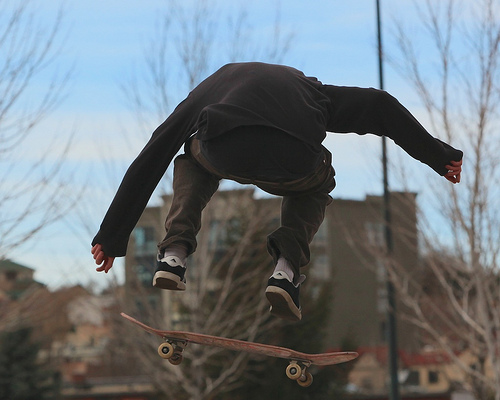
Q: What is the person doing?
A: Skateboarding.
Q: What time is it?
A: Afternoon.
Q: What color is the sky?
A: Blue.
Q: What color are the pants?
A: Brown.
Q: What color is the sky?
A: Blue.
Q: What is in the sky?
A: Clouds.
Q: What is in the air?
A: Skateboard.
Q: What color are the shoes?
A: Black and white.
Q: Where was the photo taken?
A: Outdoors somewhere.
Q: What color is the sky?
A: Blue.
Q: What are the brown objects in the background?
A: Buildings.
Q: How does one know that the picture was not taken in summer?
A: Trees do not have leaves.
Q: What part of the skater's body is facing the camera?
A: Butt.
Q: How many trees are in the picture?
A: 3.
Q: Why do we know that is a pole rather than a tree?
A: No branches.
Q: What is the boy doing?
A: Skateboarding.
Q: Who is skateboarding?
A: A boy.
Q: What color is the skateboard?
A: Red.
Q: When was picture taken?
A: During the daytime.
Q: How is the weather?
A: Clear.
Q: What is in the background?
A: A building.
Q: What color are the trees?
A: Brown.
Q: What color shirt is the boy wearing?
A: Black.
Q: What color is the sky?
A: Blue.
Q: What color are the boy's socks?
A: White.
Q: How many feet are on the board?
A: 0.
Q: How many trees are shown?
A: 5.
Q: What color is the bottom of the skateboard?
A: Red.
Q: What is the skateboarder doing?
A: A jump trick.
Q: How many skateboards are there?
A: One.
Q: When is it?
A: Daytime.